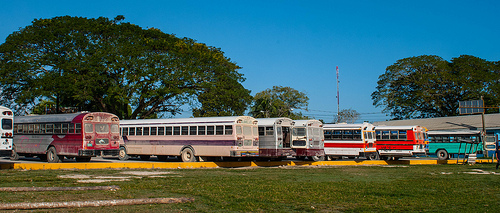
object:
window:
[135, 127, 143, 136]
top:
[424, 131, 483, 134]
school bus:
[10, 111, 122, 163]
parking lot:
[1, 152, 499, 170]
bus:
[121, 115, 262, 163]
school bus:
[259, 116, 296, 162]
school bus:
[288, 119, 325, 161]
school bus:
[373, 125, 430, 160]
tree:
[364, 52, 498, 112]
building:
[422, 115, 493, 135]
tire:
[434, 148, 450, 160]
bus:
[428, 130, 488, 161]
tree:
[365, 43, 498, 122]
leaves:
[452, 61, 476, 89]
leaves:
[213, 67, 241, 104]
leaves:
[94, 81, 128, 101]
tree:
[6, 14, 256, 117]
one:
[427, 130, 487, 160]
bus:
[324, 122, 377, 160]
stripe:
[322, 142, 374, 148]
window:
[150, 126, 180, 135]